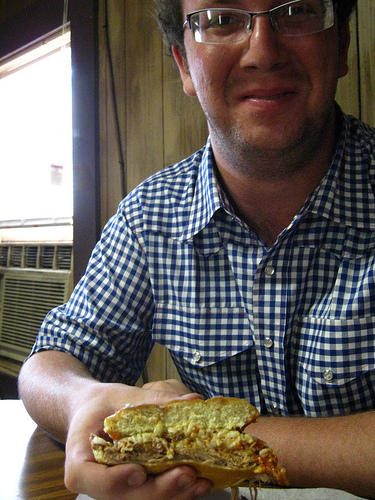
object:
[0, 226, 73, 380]
air conditioner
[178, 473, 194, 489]
fingernail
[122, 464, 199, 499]
middle finger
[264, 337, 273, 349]
3rd button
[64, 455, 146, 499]
finger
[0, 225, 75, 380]
a/c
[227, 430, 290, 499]
cheese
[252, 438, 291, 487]
tomato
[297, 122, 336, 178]
ground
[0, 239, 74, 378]
ac unit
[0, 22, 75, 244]
sunlight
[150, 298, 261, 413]
pocket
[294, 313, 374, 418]
pocket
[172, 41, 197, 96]
ear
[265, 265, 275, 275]
buttons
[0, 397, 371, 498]
table top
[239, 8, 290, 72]
nose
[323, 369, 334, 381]
button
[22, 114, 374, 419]
shirt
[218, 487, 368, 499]
white napkin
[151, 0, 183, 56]
hair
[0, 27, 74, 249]
window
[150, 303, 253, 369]
pocket flap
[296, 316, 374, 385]
pocket flap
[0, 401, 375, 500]
table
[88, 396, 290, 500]
sandwich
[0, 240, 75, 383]
unit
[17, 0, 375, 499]
man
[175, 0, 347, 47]
eyeglasses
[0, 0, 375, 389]
wall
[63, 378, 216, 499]
hand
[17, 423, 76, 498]
shadow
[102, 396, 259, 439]
bun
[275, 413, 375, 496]
arm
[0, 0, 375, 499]
room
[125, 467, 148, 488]
fingernail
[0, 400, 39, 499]
reflected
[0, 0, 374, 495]
photo